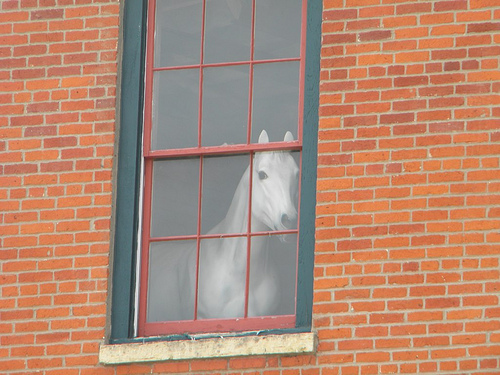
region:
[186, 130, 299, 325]
white horse looking out a window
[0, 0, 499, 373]
big brick wall of a building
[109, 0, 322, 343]
green frame of a window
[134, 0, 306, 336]
red window on a brick wall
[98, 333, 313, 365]
piece of concrete under the window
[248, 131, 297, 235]
head of a white horse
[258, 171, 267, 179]
right eye of a white horse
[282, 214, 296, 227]
black nose on a white horse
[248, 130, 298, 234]
white head of a horse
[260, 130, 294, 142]
ears of a white horse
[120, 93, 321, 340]
horse in the window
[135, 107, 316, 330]
horse is made of plastic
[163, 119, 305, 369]
horse in the window is white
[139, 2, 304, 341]
trim of the window panes is red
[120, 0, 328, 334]
green is the trim around the window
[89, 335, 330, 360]
window sill is tan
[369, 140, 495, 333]
building is made of bricks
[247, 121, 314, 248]
horse is looking out the window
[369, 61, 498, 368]
bricks are different shades of red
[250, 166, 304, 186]
horse has dark eyes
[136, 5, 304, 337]
a large window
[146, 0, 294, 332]
a red window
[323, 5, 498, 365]
bricks of the building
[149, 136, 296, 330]
a horse looking through a window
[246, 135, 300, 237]
the face of a horse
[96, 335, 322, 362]
the bottom ledge of a window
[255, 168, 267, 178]
the eye of the horse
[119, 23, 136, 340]
the green window sill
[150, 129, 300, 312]
a white horse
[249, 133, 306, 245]
the face of the horse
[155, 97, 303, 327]
the horse in the window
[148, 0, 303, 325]
the red frame of the window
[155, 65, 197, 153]
the glass panel on the window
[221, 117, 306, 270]
the head of the white horse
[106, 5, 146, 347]
the green frame of the window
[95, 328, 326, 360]
the white window seal outside on the building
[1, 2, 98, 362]
the brick wall for the building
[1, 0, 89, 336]
the white lines on the brick wall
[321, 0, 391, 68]
the lighter and darker red bricks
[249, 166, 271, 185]
the black eye of the horse in the window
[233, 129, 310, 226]
White horse standing in the window.